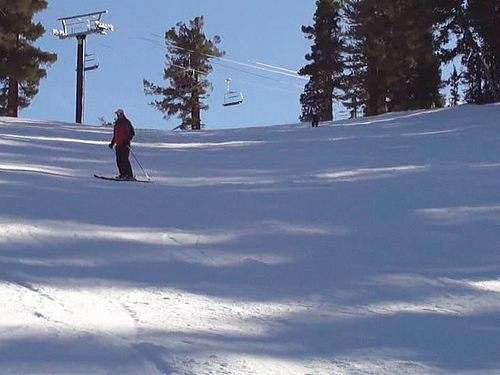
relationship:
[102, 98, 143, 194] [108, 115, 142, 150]
skier wears red jacket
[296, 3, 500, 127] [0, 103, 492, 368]
trees lining in slope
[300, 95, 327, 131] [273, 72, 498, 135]
skier in distance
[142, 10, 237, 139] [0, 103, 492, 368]
tree on snowy hill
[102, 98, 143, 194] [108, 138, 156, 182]
skier grasping ski poles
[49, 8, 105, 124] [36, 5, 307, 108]
pole of ski lift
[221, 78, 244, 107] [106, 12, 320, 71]
ski chair has wires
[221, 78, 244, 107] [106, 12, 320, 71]
ski chair attached to lift wires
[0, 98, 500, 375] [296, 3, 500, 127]
shadow of trees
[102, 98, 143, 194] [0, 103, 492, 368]
skier stands in snow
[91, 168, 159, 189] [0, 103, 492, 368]
skis in snow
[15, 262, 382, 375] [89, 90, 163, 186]
tracks left by skiers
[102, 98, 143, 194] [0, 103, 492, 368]
skier on slope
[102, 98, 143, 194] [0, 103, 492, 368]
skier traversing ski run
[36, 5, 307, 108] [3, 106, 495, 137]
ski lift on top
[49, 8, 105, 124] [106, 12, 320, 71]
pole supports lift cables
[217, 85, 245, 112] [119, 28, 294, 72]
ski chair attached to wires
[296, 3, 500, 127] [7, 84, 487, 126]
trees on top mountain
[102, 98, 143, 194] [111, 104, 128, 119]
skier has white cap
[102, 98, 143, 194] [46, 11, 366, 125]
skier holds by poles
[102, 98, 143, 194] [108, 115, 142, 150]
skier has ski jacket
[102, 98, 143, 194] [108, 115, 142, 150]
man wears coat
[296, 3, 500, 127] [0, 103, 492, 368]
trees on snow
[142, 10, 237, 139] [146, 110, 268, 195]
tree middle of truck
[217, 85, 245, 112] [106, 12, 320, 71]
car on wires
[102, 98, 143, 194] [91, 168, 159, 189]
man on ski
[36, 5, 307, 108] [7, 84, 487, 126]
ski lift in distance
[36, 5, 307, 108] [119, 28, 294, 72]
ski lift has wires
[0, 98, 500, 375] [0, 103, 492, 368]
shadow on snow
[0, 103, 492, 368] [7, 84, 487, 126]
snow on mountain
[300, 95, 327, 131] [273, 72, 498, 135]
person in distance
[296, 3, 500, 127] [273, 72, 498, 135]
trees in distance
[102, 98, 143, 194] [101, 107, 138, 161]
man in cap and glasses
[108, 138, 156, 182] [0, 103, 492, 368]
ski poles on snow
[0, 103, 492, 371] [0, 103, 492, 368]
shadow has slope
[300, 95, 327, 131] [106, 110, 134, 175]
man wearing suit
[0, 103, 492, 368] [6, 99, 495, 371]
snow covering field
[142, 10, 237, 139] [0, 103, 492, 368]
tree in background with snow